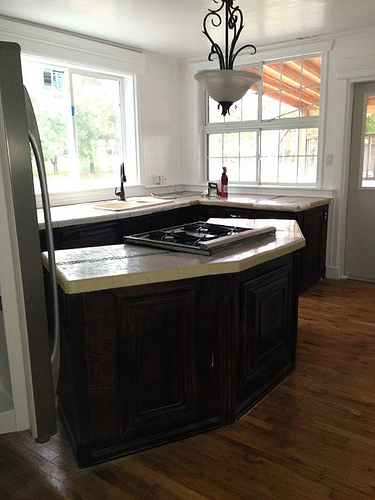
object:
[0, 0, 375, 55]
ceiling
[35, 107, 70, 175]
tree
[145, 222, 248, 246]
range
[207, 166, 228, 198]
items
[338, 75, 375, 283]
door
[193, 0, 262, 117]
fixture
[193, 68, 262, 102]
glass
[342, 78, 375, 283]
window door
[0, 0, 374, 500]
kitchen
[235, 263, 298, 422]
cabinets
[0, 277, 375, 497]
floor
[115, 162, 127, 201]
faucet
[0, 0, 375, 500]
building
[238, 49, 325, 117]
patio cover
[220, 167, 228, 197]
bottle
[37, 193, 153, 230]
counter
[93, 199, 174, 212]
sink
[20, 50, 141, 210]
window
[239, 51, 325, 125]
awning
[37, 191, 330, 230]
countertop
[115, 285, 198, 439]
cabinet door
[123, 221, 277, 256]
stove top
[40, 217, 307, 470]
island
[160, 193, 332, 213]
counter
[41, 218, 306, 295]
counter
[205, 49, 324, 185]
window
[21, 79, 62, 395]
handle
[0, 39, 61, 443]
refrigerator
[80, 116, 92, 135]
leaves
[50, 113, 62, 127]
leaves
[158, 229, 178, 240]
burner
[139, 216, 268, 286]
stove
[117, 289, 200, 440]
door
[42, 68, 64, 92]
stickers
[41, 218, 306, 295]
counter top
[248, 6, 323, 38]
light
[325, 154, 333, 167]
switch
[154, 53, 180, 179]
wall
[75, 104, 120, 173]
trees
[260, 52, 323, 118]
beams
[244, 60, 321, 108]
roof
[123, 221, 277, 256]
grill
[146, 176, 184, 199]
cords